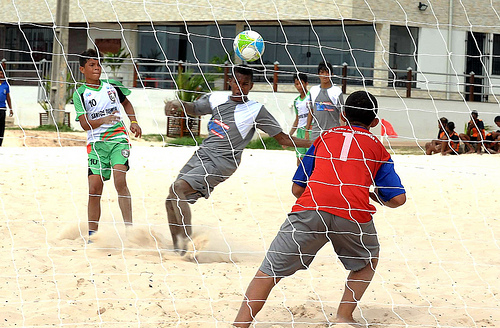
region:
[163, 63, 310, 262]
A boy running after a ball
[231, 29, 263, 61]
A ball flying through the air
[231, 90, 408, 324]
A boy waiting for the ball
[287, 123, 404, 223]
A red and blue shirt on the boy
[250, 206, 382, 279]
Gray shorts on the boy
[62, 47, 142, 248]
A boy standing in the sand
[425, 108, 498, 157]
Children sitting in the background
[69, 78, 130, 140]
A green and white shirt on the boy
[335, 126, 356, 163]
A white number on the boy's shirt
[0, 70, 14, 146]
A person in a blue shirt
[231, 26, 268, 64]
White, green and blue ball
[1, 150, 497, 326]
Sandy area around players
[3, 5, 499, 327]
net made out of white rope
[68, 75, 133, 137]
Green and white shirt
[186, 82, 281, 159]
Grey and white shirt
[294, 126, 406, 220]
Blue and red shirt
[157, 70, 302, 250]
Person about to catch the ball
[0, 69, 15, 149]
Person wearing blue in the background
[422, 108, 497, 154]
People sitting next to the wall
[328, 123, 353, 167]
The number 1 in white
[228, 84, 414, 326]
this is a man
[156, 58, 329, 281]
this is a man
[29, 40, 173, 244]
this is a man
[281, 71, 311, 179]
this is a man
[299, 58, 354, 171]
this is a man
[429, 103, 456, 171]
this is a man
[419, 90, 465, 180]
this is a man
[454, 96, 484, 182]
this is a man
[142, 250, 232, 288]
this is dust on the ground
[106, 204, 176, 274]
this is dust on the ground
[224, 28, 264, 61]
A ball in the photo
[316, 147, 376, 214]
A red and blue jersey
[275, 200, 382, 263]
A gray short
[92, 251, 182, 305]
Sand in the field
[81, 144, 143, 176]
Green shorts in the photo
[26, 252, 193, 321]
Soccer net on the goal posts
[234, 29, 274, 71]
Soccer ball in the air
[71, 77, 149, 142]
White and green jersey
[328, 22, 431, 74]
Windows on the building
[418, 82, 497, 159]
People seated in the background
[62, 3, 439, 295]
boys are playing volleyball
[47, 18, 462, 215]
white color volley ball net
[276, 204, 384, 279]
a boy wearing grey color shorts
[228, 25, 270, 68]
multi-color volley ball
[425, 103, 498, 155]
many boys are sitting in the ground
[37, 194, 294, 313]
sand in the ground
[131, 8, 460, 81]
building near the ground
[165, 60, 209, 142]
green plants in the ground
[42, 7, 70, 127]
electric post near the ground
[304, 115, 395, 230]
a boy wearing red color t-shirt